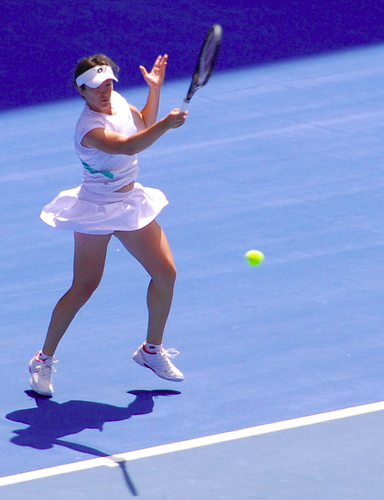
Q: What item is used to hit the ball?
A: A racket.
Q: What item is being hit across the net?
A: A ball.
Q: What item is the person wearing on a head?
A: A visor.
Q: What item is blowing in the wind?
A: A skirt.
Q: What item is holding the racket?
A: A arm.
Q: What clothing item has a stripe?
A: A shirt.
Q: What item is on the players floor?
A: A shadow.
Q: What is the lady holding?
A: A tennis racket.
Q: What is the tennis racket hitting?
A: A tennis ball.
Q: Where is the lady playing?
A: A tennis court.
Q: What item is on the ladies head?
A: A visor.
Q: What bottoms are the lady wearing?
A: A skirt.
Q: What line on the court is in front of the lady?
A: The white line.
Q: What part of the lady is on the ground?
A: Her feet.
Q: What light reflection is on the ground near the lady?
A: Her shadow.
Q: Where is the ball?
A: In front of the lady.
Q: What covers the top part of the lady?
A: Her shirt.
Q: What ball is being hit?
A: A tennis ball.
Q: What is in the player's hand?
A: A tennis racquet.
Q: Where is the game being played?
A: Tennis court.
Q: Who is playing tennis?
A: A woman.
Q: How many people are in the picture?
A: One.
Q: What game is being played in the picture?
A: Tennis.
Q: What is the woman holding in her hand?
A: A racket.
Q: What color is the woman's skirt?
A: White.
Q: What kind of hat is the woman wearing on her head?
A: Visor.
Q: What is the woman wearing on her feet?
A: Tennis shoes.